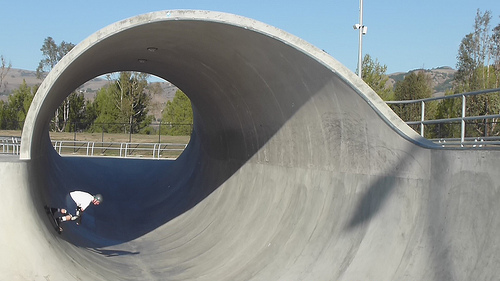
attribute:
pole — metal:
[375, 85, 440, 108]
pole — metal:
[89, 140, 96, 155]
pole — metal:
[461, 110, 496, 123]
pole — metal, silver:
[424, 92, 466, 97]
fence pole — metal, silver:
[462, 95, 465, 144]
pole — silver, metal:
[460, 91, 467, 145]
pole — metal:
[419, 97, 425, 138]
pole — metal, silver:
[412, 92, 447, 149]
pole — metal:
[53, 136, 63, 153]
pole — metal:
[421, 86, 463, 108]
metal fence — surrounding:
[386, 86, 498, 146]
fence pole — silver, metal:
[411, 87, 499, 135]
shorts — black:
[62, 190, 79, 219]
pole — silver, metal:
[423, 115, 466, 126]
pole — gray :
[355, 0, 367, 81]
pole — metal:
[463, 87, 498, 102]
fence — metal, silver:
[384, 93, 498, 143]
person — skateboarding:
[33, 133, 134, 242]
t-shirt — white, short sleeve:
[67, 186, 96, 215]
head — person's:
[90, 192, 106, 209]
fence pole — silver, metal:
[456, 96, 472, 141]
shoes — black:
[38, 195, 72, 244]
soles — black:
[43, 197, 62, 239]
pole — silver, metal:
[409, 97, 441, 151]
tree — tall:
[454, 15, 485, 144]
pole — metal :
[414, 94, 431, 144]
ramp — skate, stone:
[0, 11, 499, 277]